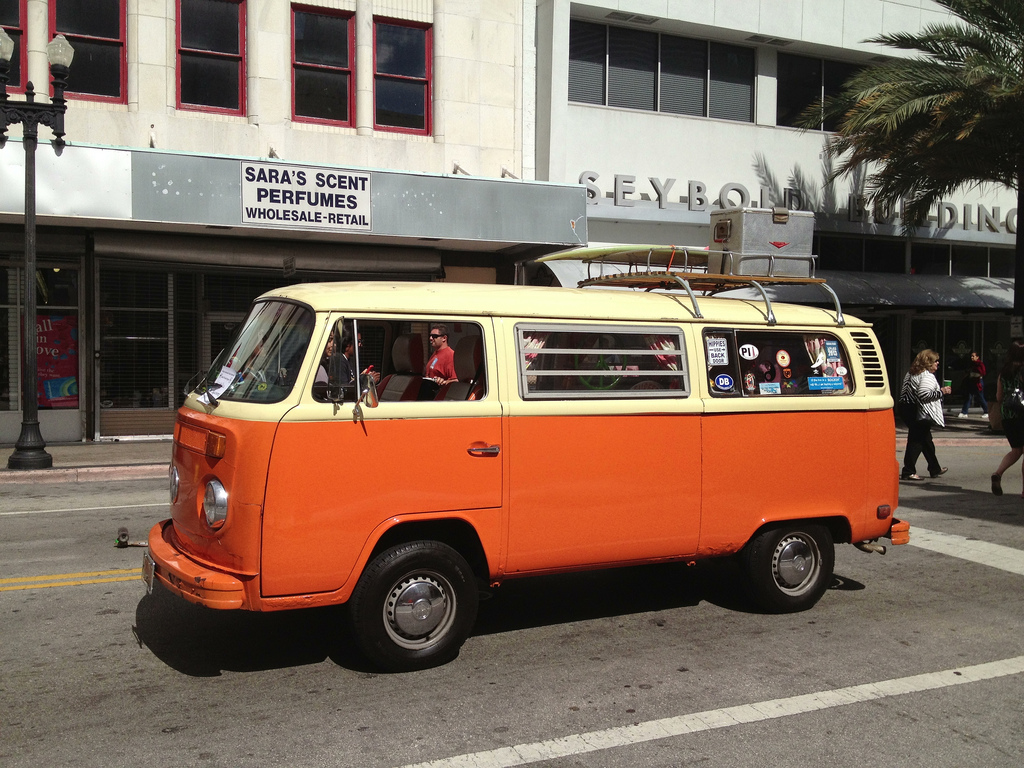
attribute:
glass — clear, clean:
[296, 70, 351, 118]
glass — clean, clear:
[361, 326, 483, 396]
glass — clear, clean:
[314, 321, 354, 398]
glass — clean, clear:
[222, 307, 306, 397]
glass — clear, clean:
[519, 324, 679, 345]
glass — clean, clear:
[520, 349, 689, 369]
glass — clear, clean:
[523, 373, 694, 393]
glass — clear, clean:
[710, 330, 851, 392]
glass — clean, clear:
[380, 77, 429, 128]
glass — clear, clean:
[375, 22, 427, 77]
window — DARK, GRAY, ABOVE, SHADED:
[573, 20, 761, 119]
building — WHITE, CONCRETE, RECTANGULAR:
[544, 0, 975, 405]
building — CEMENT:
[762, 7, 802, 137]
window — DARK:
[386, 2, 425, 127]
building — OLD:
[298, 21, 336, 139]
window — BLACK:
[204, 8, 244, 98]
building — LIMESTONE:
[67, 5, 156, 107]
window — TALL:
[137, 263, 182, 514]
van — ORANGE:
[152, 258, 906, 647]